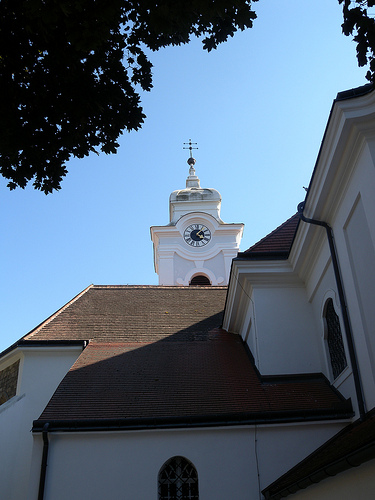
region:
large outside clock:
[151, 163, 243, 269]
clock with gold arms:
[144, 186, 251, 288]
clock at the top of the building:
[132, 185, 270, 281]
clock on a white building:
[150, 191, 257, 293]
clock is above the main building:
[143, 190, 294, 331]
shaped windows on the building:
[269, 280, 374, 390]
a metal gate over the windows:
[297, 288, 374, 404]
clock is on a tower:
[147, 184, 271, 306]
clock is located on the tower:
[153, 193, 274, 284]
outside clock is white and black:
[147, 188, 288, 307]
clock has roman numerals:
[161, 204, 245, 270]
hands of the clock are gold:
[166, 200, 224, 261]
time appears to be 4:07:
[173, 209, 221, 254]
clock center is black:
[176, 201, 218, 255]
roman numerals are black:
[166, 206, 239, 263]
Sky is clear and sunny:
[1, 0, 372, 313]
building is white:
[5, 262, 371, 498]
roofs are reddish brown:
[5, 199, 366, 433]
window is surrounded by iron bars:
[151, 454, 206, 498]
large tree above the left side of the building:
[0, 1, 265, 202]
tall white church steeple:
[149, 137, 243, 284]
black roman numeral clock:
[181, 223, 211, 247]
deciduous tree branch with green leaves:
[10, 6, 140, 191]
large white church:
[3, 85, 371, 498]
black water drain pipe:
[296, 200, 366, 414]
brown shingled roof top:
[22, 284, 353, 417]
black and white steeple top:
[182, 137, 199, 185]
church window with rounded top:
[319, 292, 350, 385]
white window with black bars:
[156, 455, 197, 498]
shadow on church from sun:
[37, 286, 237, 373]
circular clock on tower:
[180, 218, 223, 261]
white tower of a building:
[158, 128, 241, 283]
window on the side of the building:
[308, 287, 357, 396]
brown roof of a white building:
[66, 277, 259, 470]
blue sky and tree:
[15, 8, 197, 223]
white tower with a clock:
[147, 129, 257, 315]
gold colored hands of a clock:
[192, 225, 205, 242]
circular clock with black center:
[183, 221, 212, 247]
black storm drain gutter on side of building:
[286, 186, 373, 412]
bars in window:
[142, 443, 199, 497]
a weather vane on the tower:
[180, 135, 200, 158]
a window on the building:
[158, 451, 203, 499]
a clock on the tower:
[179, 220, 212, 248]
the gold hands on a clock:
[194, 223, 206, 239]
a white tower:
[142, 136, 251, 286]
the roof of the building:
[5, 280, 352, 432]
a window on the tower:
[187, 264, 214, 286]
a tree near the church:
[0, 0, 263, 197]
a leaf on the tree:
[99, 137, 122, 157]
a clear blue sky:
[0, 0, 373, 352]